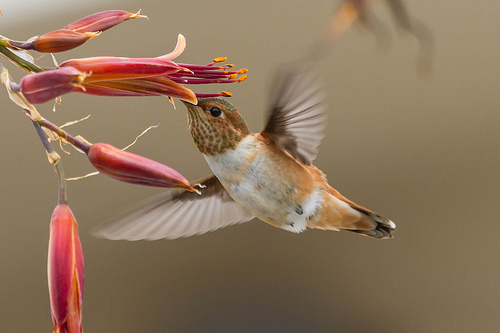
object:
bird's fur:
[204, 151, 308, 214]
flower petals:
[21, 60, 93, 102]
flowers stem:
[1, 75, 65, 146]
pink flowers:
[13, 25, 105, 52]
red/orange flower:
[88, 140, 198, 200]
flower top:
[203, 51, 252, 102]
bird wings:
[85, 168, 261, 245]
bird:
[83, 55, 400, 242]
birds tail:
[316, 179, 396, 248]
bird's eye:
[208, 102, 223, 117]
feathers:
[338, 187, 398, 244]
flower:
[47, 203, 87, 331]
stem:
[34, 116, 72, 197]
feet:
[292, 201, 305, 217]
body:
[219, 126, 330, 227]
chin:
[190, 128, 230, 149]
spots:
[205, 132, 223, 150]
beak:
[176, 89, 203, 112]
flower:
[62, 50, 252, 100]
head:
[180, 83, 260, 160]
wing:
[94, 173, 264, 245]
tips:
[88, 217, 233, 241]